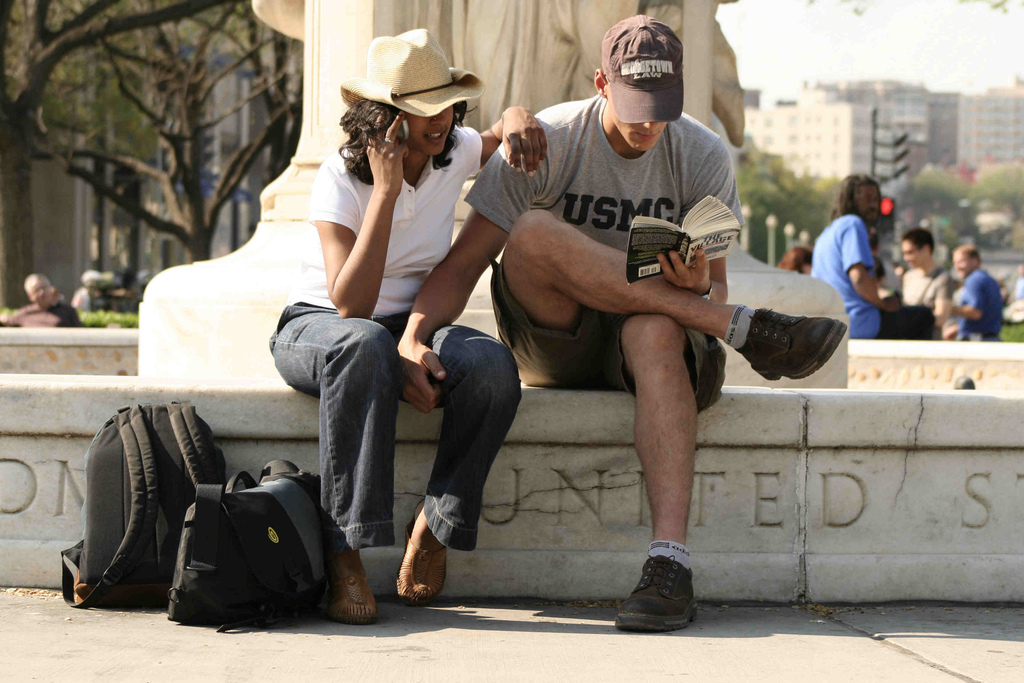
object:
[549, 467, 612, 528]
letter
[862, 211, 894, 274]
person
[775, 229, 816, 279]
person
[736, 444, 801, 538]
letter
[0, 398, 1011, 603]
wall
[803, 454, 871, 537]
letter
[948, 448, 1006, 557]
letter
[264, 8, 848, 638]
people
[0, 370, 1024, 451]
ledge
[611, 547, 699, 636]
black shoes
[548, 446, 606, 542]
letter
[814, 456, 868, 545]
letter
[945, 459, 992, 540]
letter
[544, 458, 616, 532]
letter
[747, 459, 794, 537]
letter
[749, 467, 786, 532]
letter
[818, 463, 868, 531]
letter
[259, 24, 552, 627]
woman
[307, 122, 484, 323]
shirt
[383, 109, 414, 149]
cell phone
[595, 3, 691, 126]
baseball cap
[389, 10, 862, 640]
man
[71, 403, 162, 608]
straps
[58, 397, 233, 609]
backpack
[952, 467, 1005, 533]
words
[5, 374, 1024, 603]
stone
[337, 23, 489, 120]
cowboy hat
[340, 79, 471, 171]
head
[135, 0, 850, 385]
statue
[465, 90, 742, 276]
shirt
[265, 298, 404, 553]
jeans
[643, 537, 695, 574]
sock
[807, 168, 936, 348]
man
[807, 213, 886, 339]
shirt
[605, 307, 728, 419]
shorts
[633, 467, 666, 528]
letter